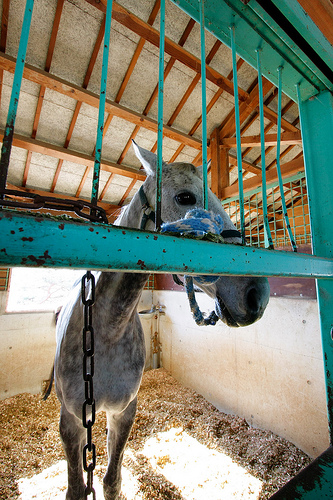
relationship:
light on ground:
[140, 427, 263, 500] [6, 408, 306, 498]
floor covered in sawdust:
[7, 383, 302, 496] [0, 417, 305, 496]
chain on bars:
[47, 265, 122, 498] [69, 0, 265, 216]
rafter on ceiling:
[115, 23, 144, 111] [1, 1, 330, 255]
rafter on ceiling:
[43, 0, 69, 79] [1, 1, 330, 255]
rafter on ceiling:
[59, 92, 82, 151] [1, 1, 330, 255]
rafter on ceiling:
[28, 73, 49, 139] [1, 1, 330, 255]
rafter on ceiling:
[49, 153, 62, 193] [1, 1, 330, 255]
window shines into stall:
[6, 266, 98, 313] [30, 104, 331, 496]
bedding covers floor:
[6, 356, 285, 497] [9, 391, 320, 498]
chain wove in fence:
[1, 188, 109, 226] [1, 50, 322, 223]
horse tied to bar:
[104, 145, 236, 247] [149, 30, 172, 216]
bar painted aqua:
[89, 1, 115, 217] [0, 0, 332, 495]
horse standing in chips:
[38, 137, 270, 500] [0, 364, 313, 498]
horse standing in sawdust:
[38, 137, 270, 500] [0, 417, 305, 496]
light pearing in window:
[140, 427, 263, 500] [6, 266, 89, 335]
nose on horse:
[229, 279, 271, 315] [38, 137, 270, 500]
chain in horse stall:
[2, 184, 112, 495] [0, 1, 323, 499]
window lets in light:
[6, 266, 98, 313] [140, 427, 253, 499]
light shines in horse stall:
[140, 427, 253, 499] [0, 1, 333, 498]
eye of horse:
[174, 188, 200, 211] [38, 137, 270, 500]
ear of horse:
[132, 140, 164, 175] [42, 274, 144, 498]